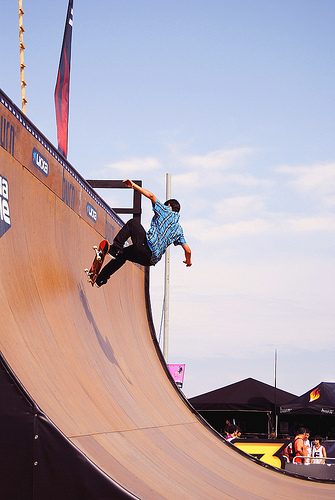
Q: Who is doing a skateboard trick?
A: A boy.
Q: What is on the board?
A: A shadow.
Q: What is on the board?
A: Logos.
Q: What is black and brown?
A: Skateboard.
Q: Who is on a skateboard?
A: A guy.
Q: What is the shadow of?
A: A guy on a skateboard.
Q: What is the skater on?
A: A slope.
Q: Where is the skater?
A: Top of slope.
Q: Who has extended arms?
A: The skater.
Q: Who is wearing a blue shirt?
A: The boy.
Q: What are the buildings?
A: The skate facility.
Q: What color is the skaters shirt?
A: Blue.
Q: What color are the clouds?
A: White.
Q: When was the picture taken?
A: During the day.